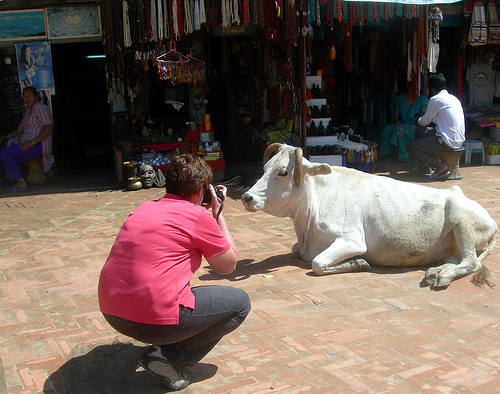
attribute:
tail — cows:
[455, 237, 499, 297]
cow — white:
[233, 124, 494, 297]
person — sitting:
[399, 68, 499, 186]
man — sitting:
[392, 52, 485, 197]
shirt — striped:
[10, 100, 57, 147]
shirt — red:
[92, 191, 233, 327]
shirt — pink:
[118, 157, 247, 357]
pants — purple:
[103, 270, 263, 387]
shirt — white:
[415, 83, 470, 143]